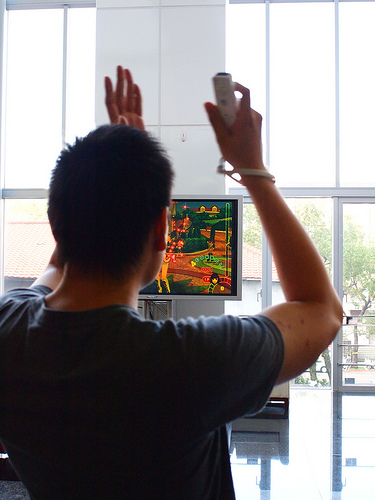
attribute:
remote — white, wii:
[211, 71, 238, 134]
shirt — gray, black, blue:
[3, 284, 284, 499]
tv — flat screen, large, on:
[117, 186, 244, 304]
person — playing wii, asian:
[1, 64, 345, 500]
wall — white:
[92, 2, 230, 344]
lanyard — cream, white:
[215, 157, 274, 182]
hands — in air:
[202, 83, 264, 169]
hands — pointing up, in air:
[101, 65, 147, 140]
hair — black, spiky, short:
[44, 123, 174, 261]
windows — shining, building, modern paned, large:
[3, 1, 375, 392]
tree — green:
[241, 196, 375, 383]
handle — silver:
[343, 314, 351, 323]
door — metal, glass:
[327, 197, 375, 392]